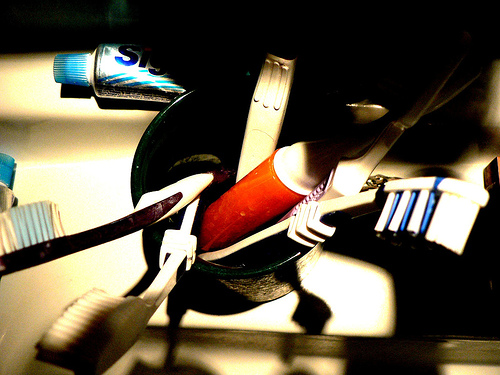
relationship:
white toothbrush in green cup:
[37, 266, 195, 374] [130, 77, 336, 278]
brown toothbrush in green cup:
[1, 198, 152, 279] [130, 77, 336, 278]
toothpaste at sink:
[53, 43, 183, 103] [1, 101, 134, 157]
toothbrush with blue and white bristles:
[287, 177, 489, 255] [373, 191, 479, 256]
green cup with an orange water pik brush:
[130, 77, 336, 278] [201, 134, 364, 254]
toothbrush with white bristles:
[37, 266, 195, 374] [26, 286, 121, 364]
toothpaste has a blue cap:
[53, 43, 183, 103] [53, 53, 91, 86]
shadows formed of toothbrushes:
[275, 263, 333, 337] [287, 177, 489, 255]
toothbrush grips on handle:
[287, 177, 489, 255] [204, 198, 340, 249]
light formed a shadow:
[183, 270, 395, 337] [165, 269, 398, 375]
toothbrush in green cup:
[287, 177, 489, 255] [130, 77, 336, 278]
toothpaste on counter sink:
[53, 43, 183, 103] [1, 101, 134, 157]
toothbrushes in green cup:
[1, 198, 152, 279] [130, 77, 336, 278]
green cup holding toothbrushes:
[130, 77, 336, 278] [1, 1, 497, 374]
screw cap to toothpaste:
[53, 53, 91, 86] [53, 43, 183, 103]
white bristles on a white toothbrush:
[26, 286, 121, 364] [37, 266, 195, 374]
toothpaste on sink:
[53, 43, 183, 103] [1, 101, 134, 157]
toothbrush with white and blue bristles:
[287, 177, 489, 255] [373, 191, 479, 256]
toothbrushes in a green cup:
[1, 1, 497, 374] [130, 77, 336, 278]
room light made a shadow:
[1, 1, 497, 374] [165, 269, 398, 375]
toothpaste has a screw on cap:
[53, 43, 183, 103] [53, 53, 91, 86]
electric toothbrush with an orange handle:
[198, 123, 327, 254] [201, 139, 306, 255]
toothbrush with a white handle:
[37, 266, 195, 374] [197, 196, 349, 264]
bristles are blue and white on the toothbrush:
[373, 191, 479, 256] [287, 177, 489, 255]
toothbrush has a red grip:
[199, 141, 322, 250] [201, 139, 306, 255]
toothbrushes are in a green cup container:
[0, 172, 219, 276] [130, 77, 336, 278]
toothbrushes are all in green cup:
[0, 172, 219, 276] [130, 77, 336, 278]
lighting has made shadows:
[1, 1, 497, 374] [165, 269, 398, 375]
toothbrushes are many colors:
[0, 172, 219, 276] [1, 1, 497, 374]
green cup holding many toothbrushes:
[130, 77, 336, 278] [1, 1, 497, 374]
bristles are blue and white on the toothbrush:
[373, 191, 479, 256] [207, 177, 488, 255]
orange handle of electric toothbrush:
[199, 141, 322, 250] [198, 123, 327, 254]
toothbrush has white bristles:
[37, 266, 195, 374] [26, 286, 121, 364]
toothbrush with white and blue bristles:
[200, 177, 489, 264] [373, 191, 479, 256]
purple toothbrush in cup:
[0, 172, 208, 276] [130, 77, 336, 278]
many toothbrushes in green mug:
[37, 266, 195, 374] [130, 77, 336, 278]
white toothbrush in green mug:
[37, 266, 195, 374] [130, 77, 336, 278]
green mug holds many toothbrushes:
[130, 77, 336, 278] [1, 1, 497, 374]